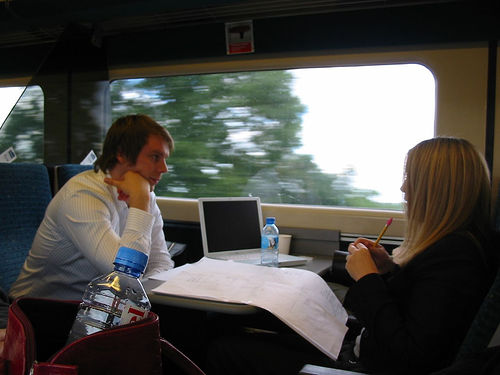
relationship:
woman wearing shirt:
[341, 133, 498, 373] [333, 230, 489, 375]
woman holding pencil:
[341, 133, 498, 373] [369, 215, 395, 249]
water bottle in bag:
[67, 247, 153, 336] [1, 296, 166, 373]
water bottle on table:
[257, 212, 282, 270] [142, 224, 343, 316]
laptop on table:
[192, 193, 313, 269] [142, 224, 343, 316]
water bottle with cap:
[67, 247, 153, 336] [111, 247, 148, 275]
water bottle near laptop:
[257, 212, 282, 270] [192, 193, 313, 269]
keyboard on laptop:
[210, 252, 306, 263] [192, 193, 313, 269]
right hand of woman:
[354, 236, 385, 256] [341, 133, 498, 373]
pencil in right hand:
[369, 215, 395, 249] [354, 236, 385, 256]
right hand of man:
[99, 167, 152, 209] [0, 112, 177, 359]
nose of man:
[157, 156, 172, 175] [0, 112, 177, 359]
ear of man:
[113, 144, 126, 166] [0, 112, 177, 359]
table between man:
[142, 224, 343, 316] [6, 114, 175, 302]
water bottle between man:
[257, 212, 282, 270] [6, 114, 175, 302]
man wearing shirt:
[0, 112, 177, 359] [9, 163, 177, 296]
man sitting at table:
[0, 112, 177, 359] [142, 224, 343, 316]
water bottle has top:
[67, 247, 153, 336] [114, 246, 150, 277]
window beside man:
[87, 63, 443, 214] [6, 114, 175, 302]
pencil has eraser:
[369, 215, 395, 249] [380, 217, 390, 230]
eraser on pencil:
[380, 217, 390, 230] [369, 215, 395, 249]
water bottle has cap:
[67, 247, 153, 336] [111, 245, 149, 275]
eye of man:
[143, 148, 165, 166] [0, 112, 177, 359]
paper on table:
[149, 256, 353, 363] [142, 224, 343, 316]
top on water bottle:
[114, 246, 150, 277] [67, 247, 153, 336]